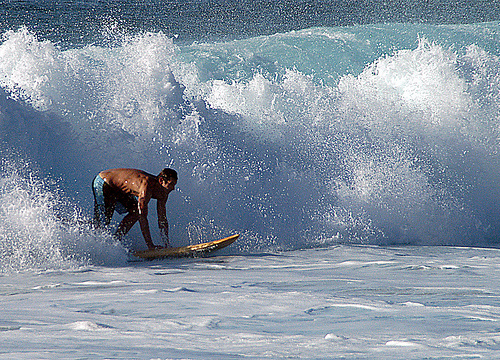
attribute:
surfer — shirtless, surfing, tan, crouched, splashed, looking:
[91, 167, 180, 257]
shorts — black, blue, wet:
[91, 172, 139, 222]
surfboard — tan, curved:
[135, 233, 239, 259]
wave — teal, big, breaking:
[2, 19, 499, 271]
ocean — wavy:
[2, 1, 497, 360]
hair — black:
[158, 167, 178, 180]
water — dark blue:
[1, 0, 498, 51]